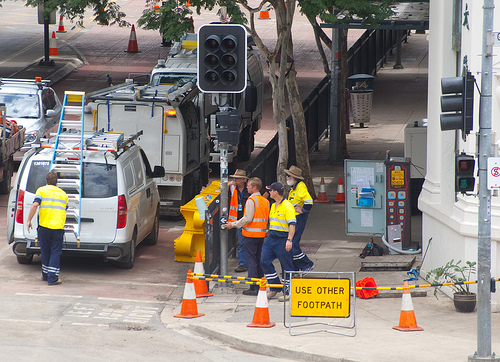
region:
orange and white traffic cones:
[177, 253, 429, 336]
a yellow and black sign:
[286, 267, 349, 322]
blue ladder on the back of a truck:
[40, 88, 92, 239]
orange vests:
[227, 194, 272, 238]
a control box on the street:
[347, 153, 414, 250]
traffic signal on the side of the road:
[197, 23, 245, 93]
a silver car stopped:
[0, 69, 72, 158]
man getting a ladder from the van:
[25, 87, 86, 278]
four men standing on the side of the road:
[225, 164, 315, 281]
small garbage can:
[347, 69, 382, 139]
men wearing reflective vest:
[228, 161, 320, 274]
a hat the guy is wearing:
[283, 162, 311, 180]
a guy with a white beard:
[281, 160, 318, 206]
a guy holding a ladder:
[24, 169, 86, 289]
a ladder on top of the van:
[47, 83, 90, 153]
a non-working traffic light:
[188, 13, 250, 111]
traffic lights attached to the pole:
[429, 39, 499, 360]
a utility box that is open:
[331, 146, 419, 270]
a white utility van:
[13, 126, 164, 297]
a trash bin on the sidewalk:
[348, 67, 377, 128]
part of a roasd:
[118, 320, 150, 349]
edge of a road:
[177, 315, 204, 348]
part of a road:
[143, 330, 158, 343]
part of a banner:
[301, 277, 344, 317]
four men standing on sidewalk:
[197, 163, 336, 299]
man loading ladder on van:
[25, 82, 100, 285]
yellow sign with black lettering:
[282, 278, 377, 338]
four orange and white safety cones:
[180, 243, 428, 342]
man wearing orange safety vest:
[228, 183, 274, 290]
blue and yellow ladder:
[42, 81, 91, 241]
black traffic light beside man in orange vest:
[194, 23, 251, 295]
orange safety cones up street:
[33, 0, 288, 71]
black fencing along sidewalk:
[235, 3, 412, 265]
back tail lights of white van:
[12, 188, 126, 223]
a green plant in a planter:
[423, 255, 478, 311]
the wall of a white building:
[418, 0, 497, 295]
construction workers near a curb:
[169, 158, 321, 357]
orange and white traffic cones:
[170, 248, 422, 331]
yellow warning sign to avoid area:
[282, 263, 357, 340]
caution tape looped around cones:
[174, 266, 479, 331]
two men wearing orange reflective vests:
[221, 165, 268, 240]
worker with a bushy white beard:
[281, 168, 313, 216]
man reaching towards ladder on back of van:
[6, 91, 164, 286]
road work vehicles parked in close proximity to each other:
[1, 29, 262, 266]